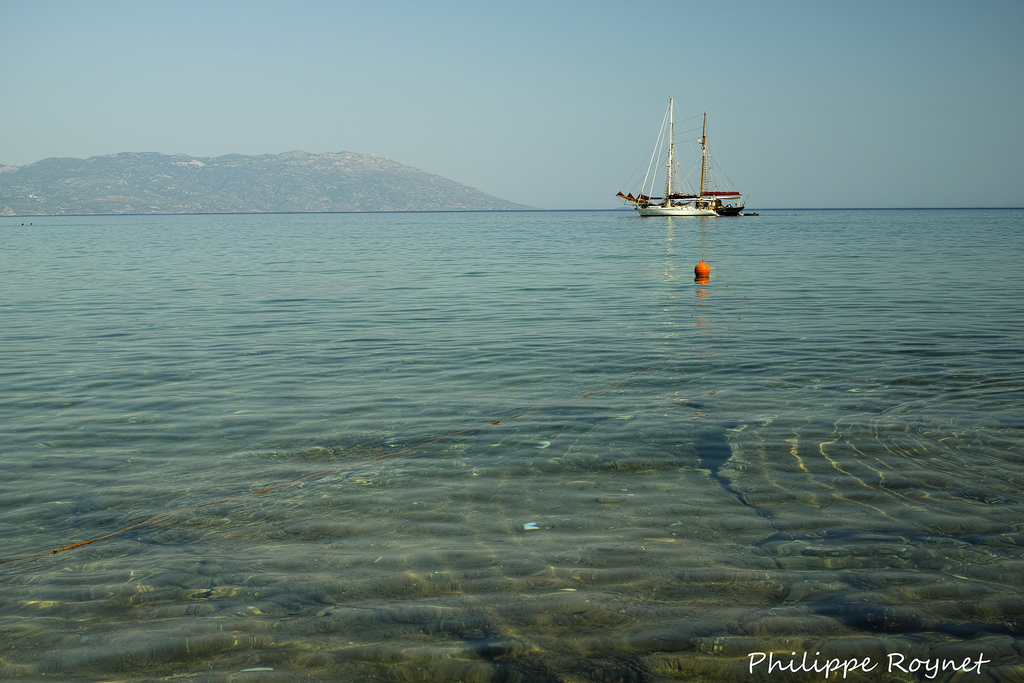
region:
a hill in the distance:
[5, 150, 525, 214]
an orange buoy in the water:
[680, 255, 720, 284]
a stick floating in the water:
[30, 498, 182, 563]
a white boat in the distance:
[615, 90, 749, 218]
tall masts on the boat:
[648, 99, 713, 191]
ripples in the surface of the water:
[177, 288, 378, 399]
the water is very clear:
[150, 443, 299, 581]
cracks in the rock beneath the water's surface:
[674, 413, 811, 607]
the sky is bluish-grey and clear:
[746, 33, 955, 163]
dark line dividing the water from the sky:
[776, 198, 1020, 217]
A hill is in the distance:
[63, 138, 498, 237]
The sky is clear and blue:
[210, 9, 849, 89]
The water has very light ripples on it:
[240, 292, 867, 565]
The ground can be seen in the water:
[382, 399, 882, 615]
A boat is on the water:
[624, 102, 749, 238]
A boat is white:
[632, 166, 741, 233]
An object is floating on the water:
[681, 246, 726, 298]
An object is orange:
[675, 236, 729, 290]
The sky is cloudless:
[705, 9, 1003, 181]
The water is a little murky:
[120, 325, 792, 639]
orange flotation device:
[672, 252, 791, 333]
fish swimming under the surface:
[391, 459, 777, 618]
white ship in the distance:
[606, 82, 772, 250]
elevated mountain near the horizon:
[3, 145, 544, 229]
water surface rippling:
[305, 357, 977, 659]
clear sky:
[6, 4, 1021, 103]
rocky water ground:
[187, 478, 832, 671]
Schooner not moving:
[594, 95, 771, 266]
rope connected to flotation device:
[15, 477, 259, 586]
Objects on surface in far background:
[15, 216, 50, 239]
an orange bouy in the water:
[689, 247, 728, 287]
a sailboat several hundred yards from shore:
[595, 69, 770, 234]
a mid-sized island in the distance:
[6, 139, 548, 226]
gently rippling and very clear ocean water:
[120, 332, 535, 513]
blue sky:
[804, 67, 1021, 201]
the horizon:
[782, 179, 1021, 234]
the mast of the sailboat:
[635, 82, 699, 191]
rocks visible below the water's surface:
[642, 451, 1022, 641]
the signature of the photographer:
[727, 641, 1021, 679]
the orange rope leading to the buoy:
[33, 337, 683, 579]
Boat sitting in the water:
[601, 85, 739, 238]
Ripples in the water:
[196, 361, 1021, 599]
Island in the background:
[3, 115, 531, 215]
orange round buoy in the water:
[677, 250, 725, 286]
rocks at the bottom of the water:
[758, 509, 1011, 604]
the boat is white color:
[632, 175, 747, 236]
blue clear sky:
[192, 10, 810, 83]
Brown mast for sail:
[632, 123, 708, 190]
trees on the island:
[104, 140, 316, 210]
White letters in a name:
[727, 619, 1006, 676]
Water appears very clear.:
[215, 426, 814, 655]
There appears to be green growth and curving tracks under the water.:
[522, 384, 976, 656]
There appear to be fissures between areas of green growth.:
[669, 420, 907, 667]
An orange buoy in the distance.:
[667, 248, 757, 340]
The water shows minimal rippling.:
[161, 229, 624, 490]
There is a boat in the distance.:
[591, 123, 816, 247]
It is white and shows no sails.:
[620, 109, 734, 252]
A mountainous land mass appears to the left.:
[31, 125, 563, 285]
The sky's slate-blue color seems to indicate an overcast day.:
[301, 66, 943, 212]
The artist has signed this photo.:
[673, 605, 898, 678]